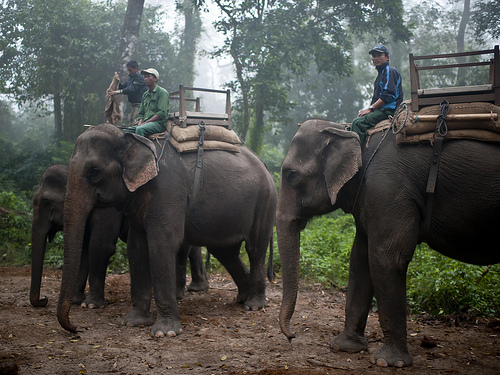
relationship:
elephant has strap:
[61, 130, 281, 316] [137, 139, 170, 160]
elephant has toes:
[61, 130, 281, 316] [139, 310, 183, 343]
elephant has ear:
[61, 130, 281, 316] [109, 143, 161, 196]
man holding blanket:
[116, 63, 144, 108] [98, 69, 131, 123]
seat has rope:
[166, 80, 236, 137] [185, 119, 218, 164]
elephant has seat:
[61, 130, 281, 316] [166, 80, 236, 137]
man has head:
[116, 63, 144, 108] [127, 55, 140, 78]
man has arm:
[116, 63, 144, 108] [109, 85, 135, 103]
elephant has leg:
[61, 130, 281, 316] [128, 230, 185, 301]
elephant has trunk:
[61, 130, 281, 316] [52, 194, 97, 276]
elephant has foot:
[61, 130, 281, 316] [124, 297, 178, 338]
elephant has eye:
[61, 130, 281, 316] [83, 165, 107, 186]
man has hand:
[116, 63, 144, 108] [104, 84, 119, 96]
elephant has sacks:
[61, 130, 281, 316] [203, 123, 237, 151]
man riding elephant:
[116, 63, 144, 108] [61, 130, 281, 316]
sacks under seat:
[203, 123, 237, 151] [166, 80, 236, 137]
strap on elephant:
[137, 139, 170, 160] [61, 130, 281, 316]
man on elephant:
[116, 63, 144, 108] [61, 130, 281, 316]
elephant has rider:
[61, 130, 281, 316] [131, 74, 171, 137]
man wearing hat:
[116, 63, 144, 108] [139, 67, 158, 79]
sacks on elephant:
[203, 123, 237, 151] [61, 130, 281, 316]